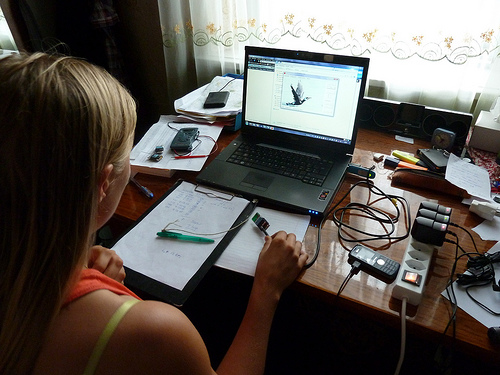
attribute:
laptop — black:
[233, 37, 358, 221]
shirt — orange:
[64, 269, 143, 299]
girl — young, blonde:
[3, 66, 273, 369]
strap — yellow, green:
[101, 289, 129, 352]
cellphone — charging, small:
[345, 243, 396, 275]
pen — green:
[158, 224, 218, 244]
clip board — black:
[130, 172, 241, 295]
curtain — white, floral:
[195, 3, 498, 102]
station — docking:
[394, 98, 427, 129]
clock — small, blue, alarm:
[431, 127, 450, 147]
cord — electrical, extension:
[257, 216, 321, 259]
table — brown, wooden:
[135, 71, 474, 321]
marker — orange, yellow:
[382, 153, 424, 170]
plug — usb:
[348, 159, 376, 186]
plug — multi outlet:
[406, 200, 432, 276]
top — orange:
[62, 273, 125, 303]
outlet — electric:
[402, 208, 432, 289]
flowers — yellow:
[196, 11, 490, 50]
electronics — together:
[223, 74, 465, 284]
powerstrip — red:
[397, 194, 430, 293]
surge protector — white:
[401, 200, 429, 310]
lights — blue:
[304, 204, 326, 221]